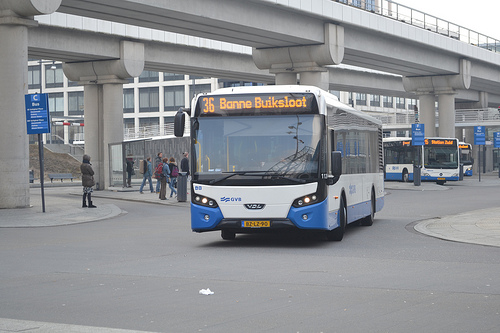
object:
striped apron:
[328, 196, 386, 229]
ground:
[0, 172, 500, 332]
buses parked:
[383, 136, 460, 185]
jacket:
[80, 154, 95, 187]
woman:
[80, 154, 95, 208]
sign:
[24, 94, 52, 135]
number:
[200, 97, 208, 113]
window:
[197, 116, 321, 173]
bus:
[172, 83, 384, 241]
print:
[201, 96, 308, 114]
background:
[0, 0, 499, 332]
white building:
[23, 51, 437, 145]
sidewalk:
[0, 193, 122, 228]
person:
[139, 155, 154, 194]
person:
[179, 151, 189, 174]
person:
[156, 156, 170, 201]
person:
[125, 154, 137, 188]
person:
[153, 151, 165, 194]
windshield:
[193, 114, 325, 178]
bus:
[383, 136, 461, 185]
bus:
[455, 141, 474, 177]